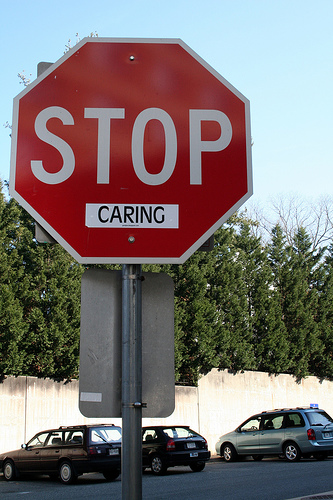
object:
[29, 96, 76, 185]
s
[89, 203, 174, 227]
sticker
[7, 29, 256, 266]
stop sign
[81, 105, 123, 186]
t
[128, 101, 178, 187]
o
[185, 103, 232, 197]
p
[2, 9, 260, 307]
region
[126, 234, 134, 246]
screw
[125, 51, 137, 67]
screw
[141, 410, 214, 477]
car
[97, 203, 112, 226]
c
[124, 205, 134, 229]
r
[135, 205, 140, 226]
i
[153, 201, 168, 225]
g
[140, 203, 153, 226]
n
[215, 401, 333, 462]
van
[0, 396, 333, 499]
parking lot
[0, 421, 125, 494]
station wagon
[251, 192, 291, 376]
trees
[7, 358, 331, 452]
wall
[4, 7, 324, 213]
sky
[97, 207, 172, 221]
caring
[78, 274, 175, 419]
back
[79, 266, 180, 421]
sign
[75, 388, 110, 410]
label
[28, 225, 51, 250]
corner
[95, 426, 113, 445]
windshield wiper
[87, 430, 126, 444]
window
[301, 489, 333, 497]
manhole cover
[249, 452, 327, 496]
roadway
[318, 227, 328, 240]
branches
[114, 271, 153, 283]
clamp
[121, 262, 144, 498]
post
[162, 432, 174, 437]
mirror